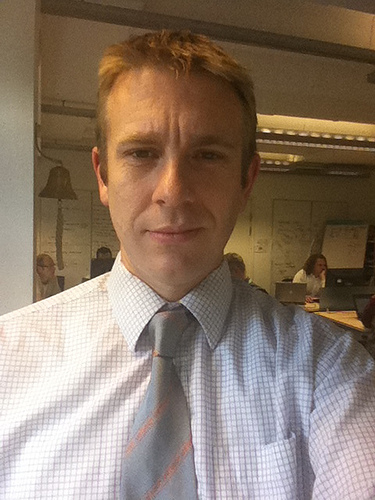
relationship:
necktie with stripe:
[119, 305, 198, 500] [138, 438, 196, 497]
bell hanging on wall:
[37, 165, 75, 200] [4, 3, 37, 311]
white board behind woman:
[268, 199, 346, 298] [288, 250, 334, 309]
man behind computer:
[0, 33, 375, 500] [84, 254, 115, 276]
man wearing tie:
[38, 40, 291, 307] [79, 288, 217, 498]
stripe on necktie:
[123, 382, 177, 452] [119, 305, 198, 500]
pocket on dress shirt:
[257, 427, 307, 498] [0, 252, 373, 499]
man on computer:
[293, 254, 328, 303] [265, 278, 317, 309]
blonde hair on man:
[83, 17, 257, 187] [0, 33, 375, 500]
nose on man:
[153, 155, 198, 206] [0, 33, 375, 500]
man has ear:
[0, 33, 375, 500] [85, 142, 119, 212]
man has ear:
[0, 33, 375, 500] [236, 143, 272, 211]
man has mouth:
[0, 33, 375, 500] [137, 220, 209, 243]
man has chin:
[0, 33, 375, 500] [121, 236, 221, 292]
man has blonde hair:
[0, 33, 375, 500] [95, 31, 257, 187]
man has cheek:
[0, 33, 375, 500] [108, 180, 143, 268]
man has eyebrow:
[0, 33, 375, 500] [191, 132, 235, 149]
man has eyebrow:
[0, 33, 375, 500] [116, 131, 162, 144]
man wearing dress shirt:
[0, 33, 375, 500] [0, 252, 373, 499]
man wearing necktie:
[0, 33, 375, 500] [116, 302, 200, 470]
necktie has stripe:
[140, 297, 237, 492] [142, 436, 191, 490]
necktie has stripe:
[140, 297, 237, 492] [119, 380, 179, 457]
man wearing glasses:
[34, 251, 62, 304] [39, 260, 55, 268]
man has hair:
[295, 251, 331, 296] [300, 252, 327, 277]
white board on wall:
[268, 199, 346, 298] [31, 143, 373, 306]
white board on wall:
[39, 189, 120, 291] [31, 143, 373, 306]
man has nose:
[0, 33, 375, 500] [150, 149, 200, 213]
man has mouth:
[0, 33, 375, 500] [143, 218, 207, 237]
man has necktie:
[0, 33, 375, 500] [119, 305, 198, 500]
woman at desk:
[290, 250, 330, 306] [309, 309, 374, 342]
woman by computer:
[290, 250, 330, 306] [317, 266, 374, 309]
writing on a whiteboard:
[41, 188, 107, 260] [254, 180, 352, 255]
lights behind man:
[252, 120, 374, 158] [0, 33, 375, 500]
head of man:
[88, 25, 261, 288] [53, 33, 253, 271]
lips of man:
[139, 221, 209, 242] [0, 33, 375, 500]